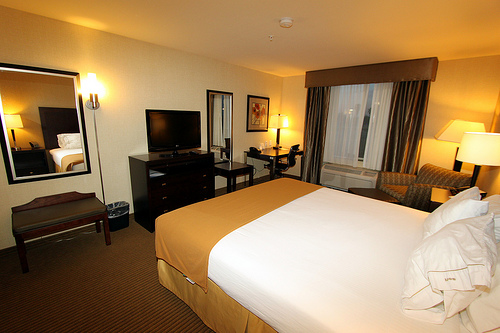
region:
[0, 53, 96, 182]
Large mirror on the wall near lamp.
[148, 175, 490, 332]
Yellow and white bed.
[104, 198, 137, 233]
Small black trash can.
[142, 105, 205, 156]
Black Television on dresser.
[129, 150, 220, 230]
Black dresser across from the bed.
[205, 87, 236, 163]
Long mirror above end table.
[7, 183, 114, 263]
Brown cushioned bench seat.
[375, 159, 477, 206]
Brown and gold striped upholstered chair.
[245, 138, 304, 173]
Black desk and chair in corner.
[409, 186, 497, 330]
Large white pillows on the bed.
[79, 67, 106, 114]
light on wall of room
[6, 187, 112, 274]
bench in room by mirror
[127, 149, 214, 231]
set of drawers and desk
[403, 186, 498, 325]
white pillows on bed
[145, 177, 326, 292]
tan blanket at foot of bed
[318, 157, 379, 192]
heat and air unit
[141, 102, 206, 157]
television on stand in front of bed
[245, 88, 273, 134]
picture on the wall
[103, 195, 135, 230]
trash can on floor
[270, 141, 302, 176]
chair at desk in corner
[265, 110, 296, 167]
a lamp on the table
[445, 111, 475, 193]
a lamp on the table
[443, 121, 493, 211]
a lamp on the table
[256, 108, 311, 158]
a lamp on the table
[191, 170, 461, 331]
the bed is made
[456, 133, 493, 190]
lamp on the floor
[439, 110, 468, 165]
lamp on the floor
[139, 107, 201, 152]
tv on the dresser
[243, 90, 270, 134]
framed print on wall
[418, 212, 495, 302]
pillow on the bed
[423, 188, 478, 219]
pillow on the bed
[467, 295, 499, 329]
pillow on the bed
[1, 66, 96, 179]
mirror on the wall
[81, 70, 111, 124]
lamp on the wall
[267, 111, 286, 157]
a lamp in the corner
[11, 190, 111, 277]
a stool by a wall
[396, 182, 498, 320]
pillows on a bed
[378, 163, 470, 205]
a chair in the corner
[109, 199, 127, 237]
a black trash can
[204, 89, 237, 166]
a mirror on the wall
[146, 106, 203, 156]
a flat sceen tv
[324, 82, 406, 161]
a window on the wall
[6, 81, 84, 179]
a reflection in the mirror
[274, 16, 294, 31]
a smoke dector on the ceiling